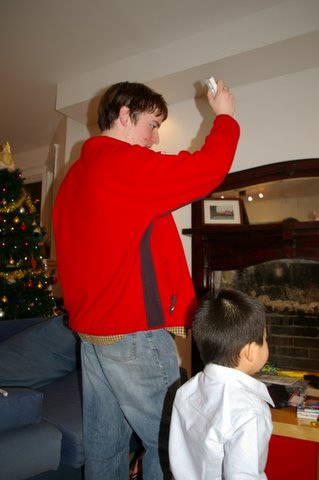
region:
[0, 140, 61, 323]
christmas tree in the background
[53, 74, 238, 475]
man playing the wii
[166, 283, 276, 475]
boy in white shirt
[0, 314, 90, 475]
blue couch next to man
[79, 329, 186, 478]
blue jeans on man's legs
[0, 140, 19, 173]
angel on the top of the tree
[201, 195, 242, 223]
picture frame on a shelf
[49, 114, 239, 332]
red jacket on the man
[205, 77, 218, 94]
wii game controller in the man's hand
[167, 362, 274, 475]
white shirt on the boy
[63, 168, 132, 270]
man wearing a red sweater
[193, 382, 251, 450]
boy wearing a white collard shirt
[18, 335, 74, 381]
a blue couch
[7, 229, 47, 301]
a christmas tree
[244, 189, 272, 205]
lights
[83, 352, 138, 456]
the jeans are blue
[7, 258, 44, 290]
ornaments on the christmas tree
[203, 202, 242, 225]
a picture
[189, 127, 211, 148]
shadow on the wall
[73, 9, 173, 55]
the ceiling is white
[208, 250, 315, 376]
A fireplace.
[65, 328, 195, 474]
The man is wearing jeans.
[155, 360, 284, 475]
The boy is wearing a white shirt.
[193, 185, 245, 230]
A picture on the mantelpiece.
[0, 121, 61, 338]
A christmas tree.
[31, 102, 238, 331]
The man is wearing a red jacket.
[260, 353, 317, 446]
A coffee table with items on it.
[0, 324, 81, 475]
A blue couch.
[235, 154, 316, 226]
A mirror in the mantelpiece.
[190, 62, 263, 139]
A video game controller is in the man's hand.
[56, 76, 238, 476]
man standing in living room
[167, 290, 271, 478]
child standing in living room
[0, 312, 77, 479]
a dark blue chair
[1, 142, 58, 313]
a decorated Christmas tree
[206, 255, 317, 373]
a brick fireplace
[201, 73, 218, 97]
a white Wii remote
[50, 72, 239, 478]
man playing a video game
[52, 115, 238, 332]
a bright red jacket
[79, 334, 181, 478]
a pair of men's jeans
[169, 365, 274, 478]
a boy's white dress shirt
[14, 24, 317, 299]
a man playing the wii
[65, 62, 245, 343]
a man with arm in the air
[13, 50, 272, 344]
a man wearing a jacket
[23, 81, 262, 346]
a man wearing a orange jacket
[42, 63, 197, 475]
a man standing up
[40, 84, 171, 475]
a man wearing jeans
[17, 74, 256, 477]
man wearing blue jeans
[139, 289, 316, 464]
a kid with short hair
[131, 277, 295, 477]
a kid wearing a shirt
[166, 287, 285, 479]
a kid wearing a collared shirt